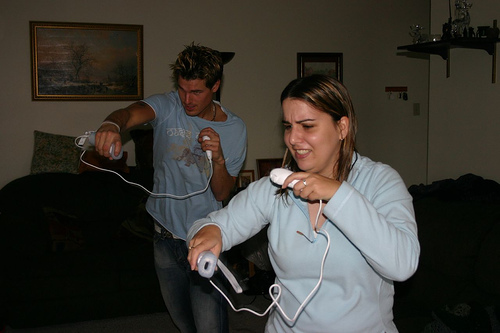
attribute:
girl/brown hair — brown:
[278, 74, 357, 176]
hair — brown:
[171, 41, 225, 88]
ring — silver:
[298, 175, 310, 187]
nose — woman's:
[289, 123, 302, 144]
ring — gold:
[186, 246, 193, 248]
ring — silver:
[299, 177, 310, 187]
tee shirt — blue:
[137, 90, 254, 249]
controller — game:
[194, 124, 224, 169]